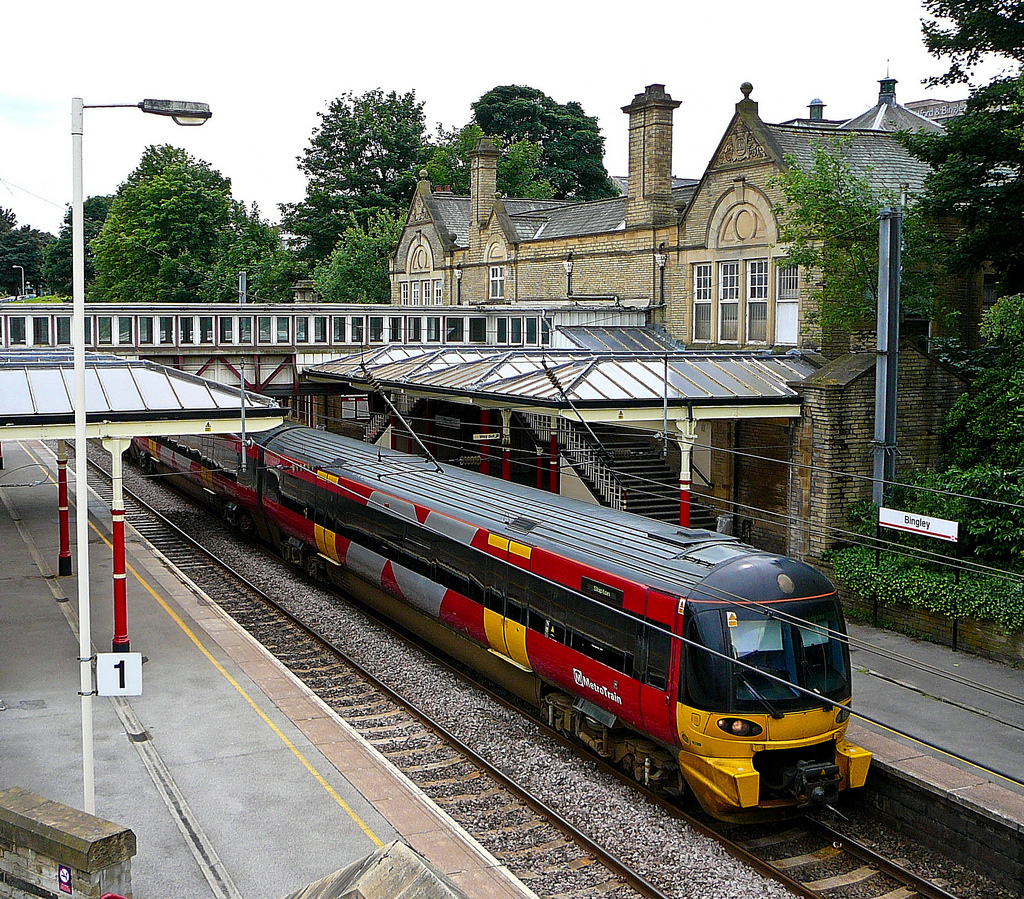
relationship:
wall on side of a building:
[516, 255, 609, 286] [397, 154, 782, 336]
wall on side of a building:
[462, 269, 493, 298] [388, 163, 814, 308]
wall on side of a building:
[542, 262, 644, 291] [401, 167, 838, 330]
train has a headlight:
[55, 339, 874, 830] [715, 714, 762, 738]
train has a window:
[306, 439, 860, 835] [719, 597, 853, 704]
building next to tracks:
[396, 94, 989, 462] [307, 613, 562, 851]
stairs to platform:
[594, 433, 806, 555] [702, 462, 994, 709]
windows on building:
[389, 528, 685, 675] [389, 72, 947, 561]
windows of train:
[728, 615, 849, 702] [265, 415, 864, 850]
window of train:
[542, 597, 640, 660] [285, 409, 886, 826]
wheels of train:
[546, 696, 680, 805] [285, 409, 886, 826]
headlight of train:
[713, 701, 763, 749] [285, 409, 886, 826]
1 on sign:
[67, 611, 147, 692] [65, 624, 264, 743]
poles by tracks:
[30, 490, 171, 659] [190, 542, 398, 735]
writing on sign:
[856, 495, 958, 548] [860, 482, 997, 576]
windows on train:
[655, 579, 859, 720] [555, 540, 837, 837]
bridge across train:
[4, 229, 644, 372] [357, 393, 759, 750]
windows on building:
[666, 251, 792, 357] [639, 197, 817, 409]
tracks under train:
[302, 637, 819, 869] [430, 503, 867, 826]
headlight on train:
[668, 704, 757, 763] [577, 520, 951, 819]